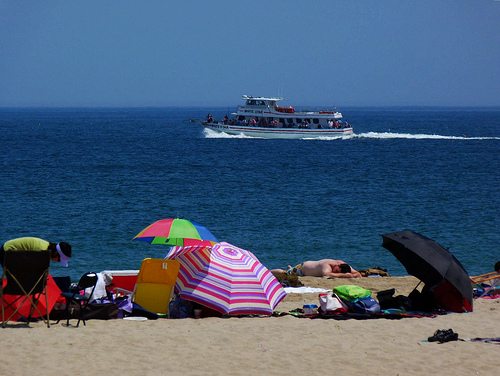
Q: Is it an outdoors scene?
A: Yes, it is outdoors.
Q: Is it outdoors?
A: Yes, it is outdoors.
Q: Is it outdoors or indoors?
A: It is outdoors.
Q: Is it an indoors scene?
A: No, it is outdoors.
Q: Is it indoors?
A: No, it is outdoors.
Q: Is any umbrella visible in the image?
A: Yes, there is an umbrella.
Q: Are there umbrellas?
A: Yes, there is an umbrella.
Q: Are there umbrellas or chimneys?
A: Yes, there is an umbrella.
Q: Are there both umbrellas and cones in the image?
A: No, there is an umbrella but no cones.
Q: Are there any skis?
A: No, there are no skis.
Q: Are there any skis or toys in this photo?
A: No, there are no skis or toys.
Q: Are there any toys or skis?
A: No, there are no skis or toys.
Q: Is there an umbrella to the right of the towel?
A: Yes, there is an umbrella to the right of the towel.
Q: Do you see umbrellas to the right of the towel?
A: Yes, there is an umbrella to the right of the towel.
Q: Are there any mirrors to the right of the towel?
A: No, there is an umbrella to the right of the towel.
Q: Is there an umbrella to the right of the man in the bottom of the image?
A: Yes, there is an umbrella to the right of the man.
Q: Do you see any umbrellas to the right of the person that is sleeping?
A: Yes, there is an umbrella to the right of the man.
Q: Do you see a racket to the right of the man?
A: No, there is an umbrella to the right of the man.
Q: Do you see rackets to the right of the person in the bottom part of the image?
A: No, there is an umbrella to the right of the man.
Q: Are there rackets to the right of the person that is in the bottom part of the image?
A: No, there is an umbrella to the right of the man.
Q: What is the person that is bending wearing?
A: The person is wearing a cap.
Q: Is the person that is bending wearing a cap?
A: Yes, the person is wearing a cap.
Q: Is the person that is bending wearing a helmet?
A: No, the person is wearing a cap.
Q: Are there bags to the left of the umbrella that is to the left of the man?
A: No, there is a person to the left of the umbrella.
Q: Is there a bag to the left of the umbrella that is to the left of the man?
A: No, there is a person to the left of the umbrella.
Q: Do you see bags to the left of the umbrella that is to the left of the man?
A: No, there is a person to the left of the umbrella.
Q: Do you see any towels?
A: Yes, there is a towel.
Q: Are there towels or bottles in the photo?
A: Yes, there is a towel.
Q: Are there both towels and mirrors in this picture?
A: No, there is a towel but no mirrors.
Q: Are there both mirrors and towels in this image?
A: No, there is a towel but no mirrors.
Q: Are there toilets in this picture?
A: No, there are no toilets.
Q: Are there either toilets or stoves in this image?
A: No, there are no toilets or stoves.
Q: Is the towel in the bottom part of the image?
A: Yes, the towel is in the bottom of the image.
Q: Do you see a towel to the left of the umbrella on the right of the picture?
A: Yes, there is a towel to the left of the umbrella.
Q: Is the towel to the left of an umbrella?
A: Yes, the towel is to the left of an umbrella.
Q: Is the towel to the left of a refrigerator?
A: No, the towel is to the left of an umbrella.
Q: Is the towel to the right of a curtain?
A: No, the towel is to the right of the umbrella.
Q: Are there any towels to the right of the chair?
A: Yes, there is a towel to the right of the chair.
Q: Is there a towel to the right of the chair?
A: Yes, there is a towel to the right of the chair.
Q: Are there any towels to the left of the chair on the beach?
A: No, the towel is to the right of the chair.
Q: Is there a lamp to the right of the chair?
A: No, there is a towel to the right of the chair.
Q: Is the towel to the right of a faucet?
A: No, the towel is to the right of the chair.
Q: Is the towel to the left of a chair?
A: No, the towel is to the right of a chair.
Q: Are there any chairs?
A: Yes, there is a chair.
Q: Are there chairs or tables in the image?
A: Yes, there is a chair.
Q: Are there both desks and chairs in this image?
A: No, there is a chair but no desks.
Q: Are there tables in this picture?
A: No, there are no tables.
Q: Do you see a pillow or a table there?
A: No, there are no tables or pillows.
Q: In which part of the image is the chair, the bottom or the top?
A: The chair is in the bottom of the image.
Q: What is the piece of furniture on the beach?
A: The piece of furniture is a chair.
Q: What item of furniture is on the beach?
A: The piece of furniture is a chair.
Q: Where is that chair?
A: The chair is on the beach.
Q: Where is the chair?
A: The chair is on the beach.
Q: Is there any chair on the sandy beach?
A: Yes, there is a chair on the beach.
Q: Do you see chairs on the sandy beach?
A: Yes, there is a chair on the beach.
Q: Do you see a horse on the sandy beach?
A: No, there is a chair on the beach.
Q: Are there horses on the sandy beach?
A: No, there is a chair on the beach.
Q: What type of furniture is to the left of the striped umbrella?
A: The piece of furniture is a chair.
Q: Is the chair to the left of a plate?
A: No, the chair is to the left of the umbrella.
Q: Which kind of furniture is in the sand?
A: The piece of furniture is a chair.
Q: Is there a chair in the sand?
A: Yes, there is a chair in the sand.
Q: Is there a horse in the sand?
A: No, there is a chair in the sand.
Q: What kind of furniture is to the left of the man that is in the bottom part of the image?
A: The piece of furniture is a chair.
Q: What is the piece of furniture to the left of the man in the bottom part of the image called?
A: The piece of furniture is a chair.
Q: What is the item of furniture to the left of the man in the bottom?
A: The piece of furniture is a chair.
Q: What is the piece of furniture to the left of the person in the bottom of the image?
A: The piece of furniture is a chair.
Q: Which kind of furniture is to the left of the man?
A: The piece of furniture is a chair.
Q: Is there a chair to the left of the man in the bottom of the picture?
A: Yes, there is a chair to the left of the man.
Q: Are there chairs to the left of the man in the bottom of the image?
A: Yes, there is a chair to the left of the man.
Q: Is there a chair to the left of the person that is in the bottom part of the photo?
A: Yes, there is a chair to the left of the man.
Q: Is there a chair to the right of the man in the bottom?
A: No, the chair is to the left of the man.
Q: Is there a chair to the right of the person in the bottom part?
A: No, the chair is to the left of the man.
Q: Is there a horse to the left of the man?
A: No, there is a chair to the left of the man.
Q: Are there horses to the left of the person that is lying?
A: No, there is a chair to the left of the man.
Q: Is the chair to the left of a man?
A: Yes, the chair is to the left of a man.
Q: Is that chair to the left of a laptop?
A: No, the chair is to the left of a man.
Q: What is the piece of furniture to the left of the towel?
A: The piece of furniture is a chair.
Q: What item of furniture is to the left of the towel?
A: The piece of furniture is a chair.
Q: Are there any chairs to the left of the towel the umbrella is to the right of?
A: Yes, there is a chair to the left of the towel.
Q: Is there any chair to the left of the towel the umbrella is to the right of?
A: Yes, there is a chair to the left of the towel.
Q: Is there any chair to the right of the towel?
A: No, the chair is to the left of the towel.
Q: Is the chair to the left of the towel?
A: Yes, the chair is to the left of the towel.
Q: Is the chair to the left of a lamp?
A: No, the chair is to the left of the towel.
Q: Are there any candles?
A: No, there are no candles.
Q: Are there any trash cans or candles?
A: No, there are no candles or trash cans.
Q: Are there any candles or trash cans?
A: No, there are no candles or trash cans.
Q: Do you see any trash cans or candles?
A: No, there are no candles or trash cans.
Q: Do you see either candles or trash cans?
A: No, there are no candles or trash cans.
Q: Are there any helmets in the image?
A: No, there are no helmets.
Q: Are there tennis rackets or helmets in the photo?
A: No, there are no helmets or tennis rackets.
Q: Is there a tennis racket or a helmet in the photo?
A: No, there are no helmets or rackets.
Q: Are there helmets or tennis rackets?
A: No, there are no helmets or tennis rackets.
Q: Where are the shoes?
A: The shoes are in the sand.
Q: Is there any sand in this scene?
A: Yes, there is sand.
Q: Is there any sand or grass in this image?
A: Yes, there is sand.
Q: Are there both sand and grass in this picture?
A: No, there is sand but no grass.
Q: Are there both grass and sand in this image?
A: No, there is sand but no grass.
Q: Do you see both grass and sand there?
A: No, there is sand but no grass.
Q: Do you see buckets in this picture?
A: No, there are no buckets.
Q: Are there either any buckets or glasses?
A: No, there are no buckets or glasses.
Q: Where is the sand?
A: The sand is on the beach.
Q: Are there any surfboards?
A: No, there are no surfboards.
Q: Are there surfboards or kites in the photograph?
A: No, there are no surfboards or kites.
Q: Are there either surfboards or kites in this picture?
A: No, there are no surfboards or kites.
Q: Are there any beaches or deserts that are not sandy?
A: No, there is a beach but it is sandy.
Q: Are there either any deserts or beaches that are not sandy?
A: No, there is a beach but it is sandy.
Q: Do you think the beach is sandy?
A: Yes, the beach is sandy.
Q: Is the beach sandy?
A: Yes, the beach is sandy.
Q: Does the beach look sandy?
A: Yes, the beach is sandy.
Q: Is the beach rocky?
A: No, the beach is sandy.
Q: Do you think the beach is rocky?
A: No, the beach is sandy.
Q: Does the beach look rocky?
A: No, the beach is sandy.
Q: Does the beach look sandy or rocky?
A: The beach is sandy.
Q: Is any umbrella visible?
A: Yes, there is an umbrella.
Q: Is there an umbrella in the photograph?
A: Yes, there is an umbrella.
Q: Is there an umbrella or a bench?
A: Yes, there is an umbrella.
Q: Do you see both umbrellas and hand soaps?
A: No, there is an umbrella but no hand soaps.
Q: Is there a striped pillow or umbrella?
A: Yes, there is a striped umbrella.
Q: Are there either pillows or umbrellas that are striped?
A: Yes, the umbrella is striped.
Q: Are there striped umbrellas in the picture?
A: Yes, there is a striped umbrella.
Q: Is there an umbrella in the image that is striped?
A: Yes, there is an umbrella that is striped.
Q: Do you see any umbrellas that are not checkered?
A: Yes, there is a striped umbrella.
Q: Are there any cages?
A: No, there are no cages.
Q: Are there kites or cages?
A: No, there are no cages or kites.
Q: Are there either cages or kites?
A: No, there are no cages or kites.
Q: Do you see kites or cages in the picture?
A: No, there are no cages or kites.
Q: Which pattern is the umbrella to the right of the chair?
A: The umbrella is striped.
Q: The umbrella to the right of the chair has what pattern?
A: The umbrella is striped.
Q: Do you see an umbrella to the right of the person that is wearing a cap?
A: Yes, there is an umbrella to the right of the person.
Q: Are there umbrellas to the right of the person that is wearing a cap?
A: Yes, there is an umbrella to the right of the person.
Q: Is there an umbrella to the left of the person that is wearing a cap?
A: No, the umbrella is to the right of the person.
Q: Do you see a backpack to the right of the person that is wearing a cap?
A: No, there is an umbrella to the right of the person.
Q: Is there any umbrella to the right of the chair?
A: Yes, there is an umbrella to the right of the chair.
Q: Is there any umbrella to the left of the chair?
A: No, the umbrella is to the right of the chair.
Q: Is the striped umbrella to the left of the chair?
A: No, the umbrella is to the right of the chair.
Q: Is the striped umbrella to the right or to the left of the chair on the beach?
A: The umbrella is to the right of the chair.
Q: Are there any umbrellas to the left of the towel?
A: Yes, there is an umbrella to the left of the towel.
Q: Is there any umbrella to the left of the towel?
A: Yes, there is an umbrella to the left of the towel.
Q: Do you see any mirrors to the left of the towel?
A: No, there is an umbrella to the left of the towel.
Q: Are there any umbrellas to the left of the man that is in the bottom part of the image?
A: Yes, there is an umbrella to the left of the man.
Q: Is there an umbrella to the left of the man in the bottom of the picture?
A: Yes, there is an umbrella to the left of the man.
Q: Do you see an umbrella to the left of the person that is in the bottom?
A: Yes, there is an umbrella to the left of the man.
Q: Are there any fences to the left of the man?
A: No, there is an umbrella to the left of the man.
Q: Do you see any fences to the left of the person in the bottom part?
A: No, there is an umbrella to the left of the man.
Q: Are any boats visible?
A: Yes, there is a boat.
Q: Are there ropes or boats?
A: Yes, there is a boat.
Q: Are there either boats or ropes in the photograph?
A: Yes, there is a boat.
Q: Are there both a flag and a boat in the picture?
A: No, there is a boat but no flags.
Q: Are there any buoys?
A: No, there are no buoys.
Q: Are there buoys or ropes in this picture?
A: No, there are no buoys or ropes.